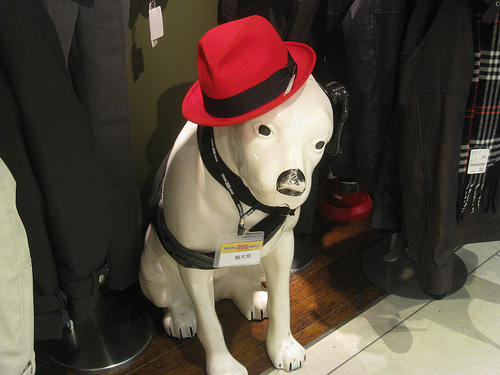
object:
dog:
[139, 68, 337, 374]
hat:
[181, 14, 316, 126]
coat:
[0, 0, 115, 342]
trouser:
[48, 2, 141, 292]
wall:
[126, 1, 220, 226]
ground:
[30, 214, 499, 374]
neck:
[194, 125, 301, 215]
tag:
[213, 233, 265, 270]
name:
[234, 253, 254, 259]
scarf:
[456, 1, 499, 219]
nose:
[276, 168, 309, 195]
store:
[0, 1, 500, 374]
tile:
[355, 300, 495, 369]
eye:
[257, 125, 272, 137]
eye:
[314, 138, 326, 150]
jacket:
[394, 4, 476, 297]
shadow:
[165, 132, 223, 253]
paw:
[264, 333, 308, 371]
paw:
[205, 356, 250, 374]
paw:
[162, 305, 198, 339]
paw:
[240, 286, 272, 320]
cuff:
[416, 255, 455, 295]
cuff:
[67, 260, 100, 324]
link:
[97, 273, 105, 283]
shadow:
[336, 250, 500, 354]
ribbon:
[201, 52, 302, 118]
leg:
[178, 264, 228, 353]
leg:
[260, 231, 295, 333]